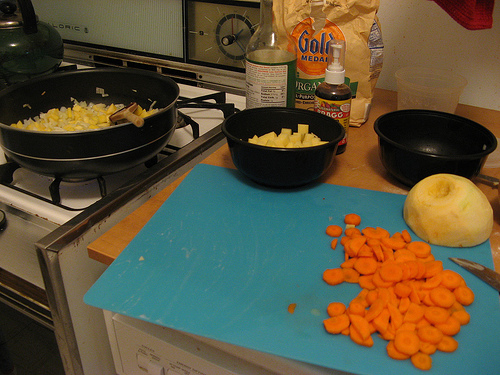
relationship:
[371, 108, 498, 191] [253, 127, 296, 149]
bowl of cheese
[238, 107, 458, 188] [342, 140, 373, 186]
bowls on counter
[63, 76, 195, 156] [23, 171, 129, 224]
pot on stove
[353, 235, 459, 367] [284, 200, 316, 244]
carrots on board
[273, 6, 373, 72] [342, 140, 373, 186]
flour on counter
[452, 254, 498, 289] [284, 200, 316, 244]
knife on board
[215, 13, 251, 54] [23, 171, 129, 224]
timer on stove